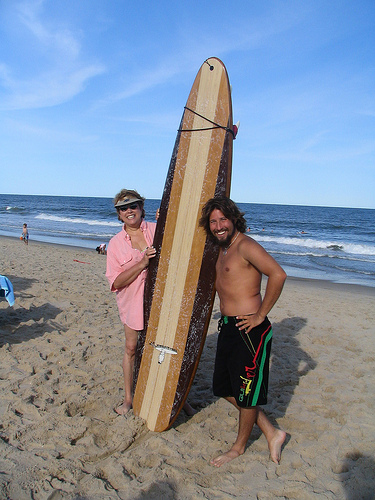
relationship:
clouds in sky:
[1, 4, 134, 185] [287, 84, 331, 122]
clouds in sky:
[1, 4, 116, 147] [99, 46, 156, 86]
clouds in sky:
[1, 4, 134, 185] [19, 32, 162, 94]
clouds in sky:
[264, 39, 352, 94] [245, 35, 320, 98]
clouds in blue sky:
[1, 4, 134, 185] [0, 0, 373, 208]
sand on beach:
[329, 313, 356, 358] [27, 187, 98, 369]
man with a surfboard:
[190, 184, 294, 474] [127, 53, 241, 437]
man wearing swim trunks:
[190, 184, 294, 474] [211, 313, 279, 405]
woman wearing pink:
[100, 170, 170, 417] [101, 219, 158, 333]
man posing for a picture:
[190, 184, 294, 474] [4, 2, 370, 324]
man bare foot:
[190, 184, 294, 474] [213, 430, 298, 464]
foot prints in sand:
[183, 428, 253, 481] [4, 237, 372, 498]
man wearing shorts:
[169, 184, 332, 410] [211, 316, 283, 405]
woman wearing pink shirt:
[100, 170, 170, 417] [94, 248, 223, 357]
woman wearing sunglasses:
[79, 170, 170, 339] [104, 199, 148, 213]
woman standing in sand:
[100, 170, 170, 417] [297, 289, 352, 330]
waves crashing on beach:
[273, 223, 309, 256] [0, 192, 373, 496]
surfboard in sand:
[122, 56, 236, 421] [1, 380, 104, 473]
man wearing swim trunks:
[190, 184, 294, 474] [211, 313, 279, 413]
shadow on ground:
[257, 315, 313, 418] [6, 202, 374, 499]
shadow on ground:
[335, 450, 374, 498] [41, 259, 353, 491]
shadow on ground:
[137, 480, 178, 498] [41, 259, 353, 491]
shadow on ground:
[257, 315, 313, 418] [41, 259, 353, 491]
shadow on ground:
[0, 302, 68, 348] [41, 259, 353, 491]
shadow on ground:
[165, 331, 221, 430] [41, 259, 353, 491]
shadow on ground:
[335, 450, 374, 498] [277, 279, 373, 498]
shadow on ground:
[257, 315, 313, 418] [277, 279, 373, 498]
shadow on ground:
[137, 480, 178, 498] [277, 279, 373, 498]